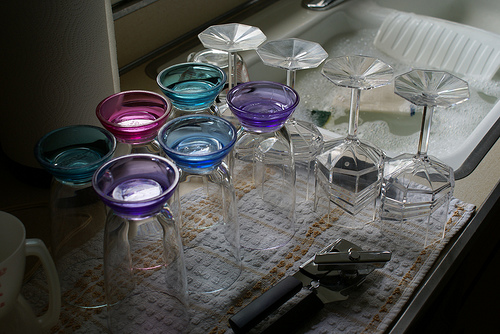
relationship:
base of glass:
[37, 62, 300, 218] [90, 152, 180, 331]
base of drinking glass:
[37, 62, 300, 218] [91, 151, 191, 327]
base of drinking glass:
[37, 62, 300, 218] [232, 80, 298, 248]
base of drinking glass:
[37, 62, 300, 218] [165, 112, 235, 294]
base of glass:
[37, 62, 300, 218] [155, 55, 226, 113]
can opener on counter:
[201, 250, 369, 317] [8, 67, 498, 331]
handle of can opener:
[230, 272, 321, 332] [230, 235, 390, 331]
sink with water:
[228, 4, 498, 175] [281, 30, 498, 156]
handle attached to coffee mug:
[18, 237, 61, 327] [0, 217, 63, 334]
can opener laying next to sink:
[228, 239, 391, 334] [228, 4, 498, 175]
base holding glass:
[154, 112, 238, 168] [160, 114, 267, 297]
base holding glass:
[37, 62, 300, 218] [218, 65, 333, 272]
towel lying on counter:
[161, 120, 466, 328] [1, 2, 481, 332]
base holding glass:
[37, 62, 300, 218] [158, 112, 243, 294]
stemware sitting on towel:
[295, 160, 486, 273] [16, 120, 476, 330]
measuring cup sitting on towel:
[1, 209, 66, 327] [88, 146, 486, 328]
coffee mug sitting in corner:
[2, 212, 63, 328] [0, 2, 65, 331]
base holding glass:
[37, 62, 300, 218] [88, 149, 194, 327]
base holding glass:
[154, 112, 238, 168] [153, 116, 263, 291]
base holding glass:
[37, 62, 300, 218] [36, 122, 134, 311]